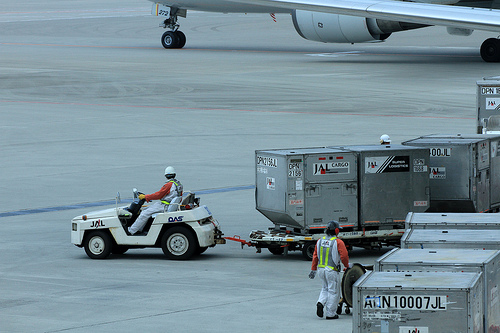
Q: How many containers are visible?
A: 10.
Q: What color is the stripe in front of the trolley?
A: Blue.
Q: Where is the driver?
A: In the cart.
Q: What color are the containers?
A: Grey.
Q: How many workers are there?
A: 3.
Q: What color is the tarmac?
A: Grey.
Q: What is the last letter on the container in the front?
A: L.